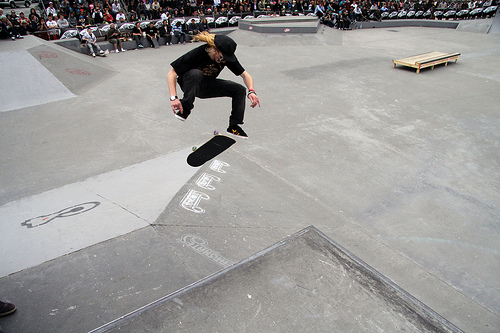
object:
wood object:
[392, 50, 462, 73]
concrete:
[304, 84, 490, 245]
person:
[145, 22, 159, 48]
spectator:
[82, 28, 105, 57]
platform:
[392, 51, 447, 69]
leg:
[215, 79, 246, 125]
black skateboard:
[186, 130, 237, 168]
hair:
[190, 30, 216, 47]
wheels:
[213, 130, 219, 136]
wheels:
[191, 146, 197, 152]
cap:
[213, 34, 237, 61]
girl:
[168, 27, 263, 139]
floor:
[10, 28, 499, 328]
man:
[167, 30, 261, 139]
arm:
[167, 47, 196, 96]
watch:
[169, 95, 178, 101]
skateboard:
[151, 36, 160, 48]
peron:
[159, 20, 173, 46]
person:
[107, 23, 126, 53]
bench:
[80, 16, 320, 55]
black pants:
[176, 78, 247, 125]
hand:
[170, 99, 184, 115]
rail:
[391, 51, 461, 74]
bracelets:
[247, 88, 258, 98]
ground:
[0, 125, 342, 330]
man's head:
[211, 34, 237, 63]